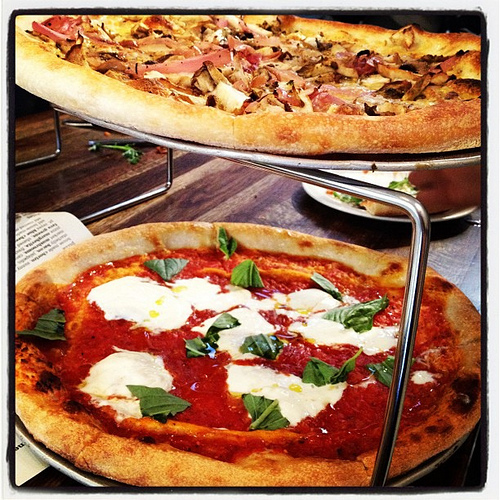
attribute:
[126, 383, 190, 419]
leaf — green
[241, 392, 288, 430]
leaf — green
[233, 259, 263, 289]
leaf — green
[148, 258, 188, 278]
leaf — green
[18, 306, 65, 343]
leaf — green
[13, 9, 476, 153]
pizza — small, round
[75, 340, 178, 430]
mozzarella — melted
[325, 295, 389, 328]
basil leaf — fresh, green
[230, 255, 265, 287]
basil leaf — fresh, green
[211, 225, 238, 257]
basil leaf — fresh, green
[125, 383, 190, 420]
basil leaf — fresh, green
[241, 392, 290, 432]
basil leaf — fresh, green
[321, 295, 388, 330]
leaves — green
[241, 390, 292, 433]
leaves — green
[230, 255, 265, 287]
leaves — green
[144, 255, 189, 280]
leaves — green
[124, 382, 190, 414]
leaves — green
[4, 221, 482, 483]
pizza — round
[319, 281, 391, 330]
leaves — green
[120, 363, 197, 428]
leaves — green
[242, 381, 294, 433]
leaves — green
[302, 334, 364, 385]
leaves — green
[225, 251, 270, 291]
leaves — green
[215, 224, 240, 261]
leaf — green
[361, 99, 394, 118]
mushroom — cooked, browned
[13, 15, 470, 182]
pizza — large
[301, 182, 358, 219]
plate — small, white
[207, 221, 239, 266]
leaf — green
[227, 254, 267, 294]
leaf — green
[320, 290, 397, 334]
leaf — green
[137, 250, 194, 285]
leaf — green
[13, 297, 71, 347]
leaf — green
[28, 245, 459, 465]
sauce — bright, red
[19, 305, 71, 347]
leaves — green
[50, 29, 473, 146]
pizza — baked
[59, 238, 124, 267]
pizza crust — crisp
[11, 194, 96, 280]
paper — white, typed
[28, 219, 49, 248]
words — black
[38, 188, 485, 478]
pizza — baked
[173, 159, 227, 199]
table — wood grain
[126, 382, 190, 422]
green — leafy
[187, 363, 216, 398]
sauce — tomato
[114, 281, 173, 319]
mozzerella — fresh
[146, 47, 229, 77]
ham — pink, sliced